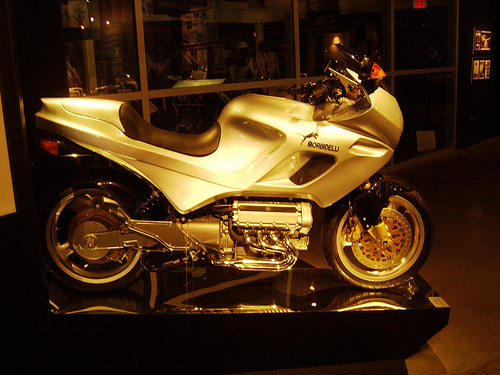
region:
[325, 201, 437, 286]
front tire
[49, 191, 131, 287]
back tire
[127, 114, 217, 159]
the seat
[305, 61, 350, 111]
the handlebars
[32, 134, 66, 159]
a backlight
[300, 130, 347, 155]
brand of the motorcycle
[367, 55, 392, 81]
front light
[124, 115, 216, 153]
the seat is black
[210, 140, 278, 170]
reflection of light on the motorcycle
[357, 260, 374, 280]
rim of the tire are grey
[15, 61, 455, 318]
motorcycle on display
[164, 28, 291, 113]
reflection in glass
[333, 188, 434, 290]
tire is silver and black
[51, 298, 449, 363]
platform is shiny and black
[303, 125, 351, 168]
logo on side of cycle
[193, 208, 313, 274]
exhaust pipe is exposed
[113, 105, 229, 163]
motorcycle seat is black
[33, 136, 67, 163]
red tail light on motorcycle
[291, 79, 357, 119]
handle bars on motorcycle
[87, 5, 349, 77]
windows in building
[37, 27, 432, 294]
futuristic motorcycle on display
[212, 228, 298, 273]
spark plug wires on the engine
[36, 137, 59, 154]
light on the rear of the cycle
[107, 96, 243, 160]
seat of the cycle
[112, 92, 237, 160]
seat of the motorcycle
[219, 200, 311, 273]
four cyclinders on this side of the cycle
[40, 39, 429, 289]
a golden motorcycle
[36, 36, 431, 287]
motorbike reflecting the light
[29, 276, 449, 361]
platform for display of the cycle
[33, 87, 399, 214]
body of the motorcycle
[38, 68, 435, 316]
Motorcycle parked on a pedestal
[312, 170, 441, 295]
Front wheel of motorcycle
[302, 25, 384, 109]
Handlebars on motorcycle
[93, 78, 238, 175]
Seat on the motorcycle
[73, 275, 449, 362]
The pedestal is reflecting light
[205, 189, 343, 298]
Engine under motorcycle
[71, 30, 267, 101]
Window behind the motorcycle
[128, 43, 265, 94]
Reflection on the glass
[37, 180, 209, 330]
Back wheel on the bike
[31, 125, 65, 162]
Brake light on the motorcycle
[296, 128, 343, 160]
chrome brand logo of motorcycle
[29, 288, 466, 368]
shiny black platform for display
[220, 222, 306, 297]
chrome exhaust mounted to motorcycle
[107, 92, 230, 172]
leather upholstered seat on motorcycle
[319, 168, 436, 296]
wheel and tire on motorcycle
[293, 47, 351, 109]
handlebar for steering on motorcycle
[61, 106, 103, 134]
silver paint job on motorcycle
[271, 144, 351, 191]
vent detailing on silver painted bike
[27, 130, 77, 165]
orange turn signal light cover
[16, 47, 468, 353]
silver motorcycle on display in show room